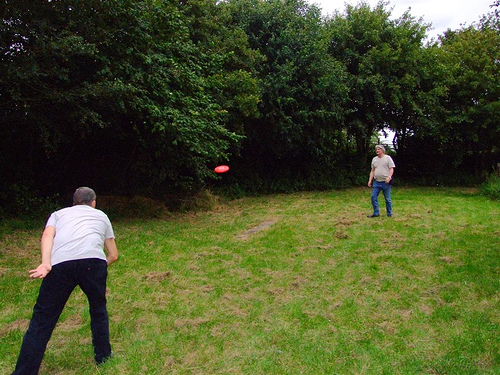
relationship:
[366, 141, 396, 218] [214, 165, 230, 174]
man playing disc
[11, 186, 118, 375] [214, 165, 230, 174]
man playing disc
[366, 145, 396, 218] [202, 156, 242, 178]
man playing frisbee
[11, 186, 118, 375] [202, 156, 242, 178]
man playing frisbee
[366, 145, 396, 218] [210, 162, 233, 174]
man waiting to catch a frisbee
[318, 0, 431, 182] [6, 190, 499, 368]
tree lining yard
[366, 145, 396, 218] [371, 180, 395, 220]
man wearing jeans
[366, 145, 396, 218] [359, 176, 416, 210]
man wearing jeans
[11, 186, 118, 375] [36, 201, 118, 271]
man wearing a shirt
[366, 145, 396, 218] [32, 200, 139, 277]
man wearing shirt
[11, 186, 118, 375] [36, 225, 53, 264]
man with arm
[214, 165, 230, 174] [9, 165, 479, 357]
disc on grass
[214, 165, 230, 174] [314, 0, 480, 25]
disc in air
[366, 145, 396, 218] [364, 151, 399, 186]
man wearing shirt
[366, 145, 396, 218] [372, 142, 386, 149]
man has hair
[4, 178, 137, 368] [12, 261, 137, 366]
man wearing jeans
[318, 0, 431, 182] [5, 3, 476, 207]
tree full leaves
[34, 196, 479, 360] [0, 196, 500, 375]
grass has grass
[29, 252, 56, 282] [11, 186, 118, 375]
hand of man